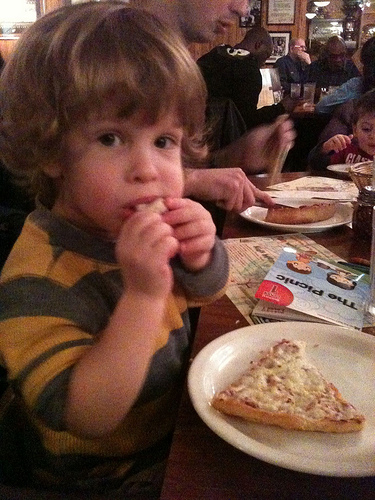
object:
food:
[225, 334, 361, 441]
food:
[131, 195, 186, 227]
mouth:
[116, 192, 163, 217]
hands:
[109, 201, 230, 291]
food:
[129, 190, 174, 225]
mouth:
[123, 188, 177, 224]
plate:
[180, 292, 373, 461]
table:
[179, 154, 373, 479]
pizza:
[216, 321, 367, 434]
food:
[124, 190, 177, 225]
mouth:
[119, 184, 172, 222]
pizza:
[229, 326, 366, 445]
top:
[352, 179, 373, 207]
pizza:
[205, 336, 367, 440]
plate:
[182, 315, 373, 480]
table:
[159, 166, 373, 495]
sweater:
[4, 195, 231, 480]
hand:
[186, 161, 271, 213]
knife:
[270, 189, 370, 209]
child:
[7, 0, 238, 494]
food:
[133, 200, 168, 216]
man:
[273, 35, 313, 82]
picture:
[235, 0, 264, 30]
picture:
[264, 2, 297, 26]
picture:
[262, 28, 294, 69]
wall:
[235, 0, 372, 44]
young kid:
[4, 60, 217, 488]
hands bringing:
[88, 188, 219, 274]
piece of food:
[128, 187, 168, 217]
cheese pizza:
[219, 321, 360, 462]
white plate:
[183, 301, 373, 475]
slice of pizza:
[222, 329, 358, 435]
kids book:
[254, 234, 368, 329]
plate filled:
[222, 334, 362, 448]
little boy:
[7, 50, 231, 485]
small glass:
[345, 162, 372, 260]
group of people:
[12, 2, 374, 182]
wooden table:
[169, 147, 373, 476]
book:
[246, 225, 373, 335]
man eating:
[147, 0, 351, 241]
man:
[139, 2, 353, 251]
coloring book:
[255, 234, 371, 344]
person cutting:
[247, 185, 347, 240]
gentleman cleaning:
[273, 32, 318, 81]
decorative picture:
[258, 28, 301, 68]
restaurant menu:
[213, 230, 362, 337]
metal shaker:
[347, 183, 374, 265]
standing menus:
[207, 230, 374, 343]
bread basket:
[205, 301, 345, 494]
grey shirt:
[8, 206, 190, 478]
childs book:
[252, 230, 374, 342]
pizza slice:
[213, 321, 358, 457]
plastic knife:
[268, 194, 308, 212]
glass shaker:
[342, 178, 371, 262]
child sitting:
[6, 54, 183, 470]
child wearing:
[10, 207, 182, 484]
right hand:
[189, 164, 338, 224]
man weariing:
[200, 26, 288, 136]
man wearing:
[191, 26, 285, 131]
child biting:
[8, 12, 226, 492]